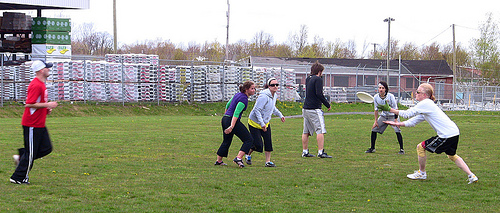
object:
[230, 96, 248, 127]
arm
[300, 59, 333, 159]
man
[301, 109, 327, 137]
shorts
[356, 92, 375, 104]
frisbee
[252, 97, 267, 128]
sleeve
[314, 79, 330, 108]
sleeve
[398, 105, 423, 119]
sleeve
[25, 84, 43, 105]
sleeve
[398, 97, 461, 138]
shirt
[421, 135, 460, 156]
shorts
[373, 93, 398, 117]
shirt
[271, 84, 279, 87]
eyes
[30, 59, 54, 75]
cap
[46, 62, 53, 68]
bill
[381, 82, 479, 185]
girl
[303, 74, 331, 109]
shirt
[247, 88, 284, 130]
shirt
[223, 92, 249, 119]
shirt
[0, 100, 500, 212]
ground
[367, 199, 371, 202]
yellow spot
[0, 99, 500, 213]
grass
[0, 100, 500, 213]
field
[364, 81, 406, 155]
people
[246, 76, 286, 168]
people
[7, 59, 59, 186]
people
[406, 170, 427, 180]
shoe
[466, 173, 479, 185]
shoe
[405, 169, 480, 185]
pair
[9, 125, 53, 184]
pants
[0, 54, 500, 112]
fence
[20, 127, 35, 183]
stripe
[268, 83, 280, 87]
shades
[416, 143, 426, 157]
patch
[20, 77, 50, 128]
shirt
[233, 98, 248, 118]
sleeve